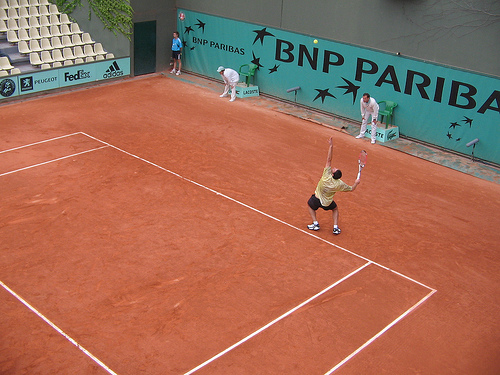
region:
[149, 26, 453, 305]
a man playing tennis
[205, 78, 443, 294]
a man on a tennis court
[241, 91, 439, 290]
a man on a dirt tennis court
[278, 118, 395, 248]
a man holding a racket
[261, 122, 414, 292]
a man holding a tennis racket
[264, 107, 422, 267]
a man swinging a racket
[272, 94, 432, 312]
a man swinging a tennis racket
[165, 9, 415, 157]
poeple standing on the side lines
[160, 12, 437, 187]
three people standing on the sidelines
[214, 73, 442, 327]
a man wearing a shirt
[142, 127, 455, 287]
a man is playing tennis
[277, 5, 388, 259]
the man is going to hit the ball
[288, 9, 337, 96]
the ball is lime green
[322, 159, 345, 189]
the man has dark hair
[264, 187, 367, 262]
the man is wearing shorts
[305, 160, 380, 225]
the man is wearing short sleeves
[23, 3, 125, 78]
the seats are empty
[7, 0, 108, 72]
the chairs are creme colored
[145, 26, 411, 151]
people standing in the background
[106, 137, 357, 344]
the ground is reddish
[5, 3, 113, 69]
rows of empty white seats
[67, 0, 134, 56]
green ivy on wall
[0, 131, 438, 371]
white lines on court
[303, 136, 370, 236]
player in a serving stance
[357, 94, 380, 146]
man in white bent over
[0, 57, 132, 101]
logos on green wall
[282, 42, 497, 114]
black letter on green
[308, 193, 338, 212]
black shorts on player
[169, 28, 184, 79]
person standing in corner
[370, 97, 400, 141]
green chair on block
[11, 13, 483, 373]
Tennis match on clay court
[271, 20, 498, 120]
BNP Paribas sponsorship sign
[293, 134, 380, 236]
Male tennis player in shorts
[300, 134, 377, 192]
Male tennis player serving ball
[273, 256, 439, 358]
White chalked side lines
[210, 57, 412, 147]
Two umpires watching match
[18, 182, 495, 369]
Red clay tennis court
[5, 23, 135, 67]
White empty seated stands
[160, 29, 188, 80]
Blue and black clad ball boy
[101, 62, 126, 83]
Black adidas sign and logo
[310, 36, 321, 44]
a small green tennis ball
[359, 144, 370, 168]
a red, white and blue racket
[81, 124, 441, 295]
a long white line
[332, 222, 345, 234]
the shoe of a man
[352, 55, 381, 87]
a black capital letter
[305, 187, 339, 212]
a man's black shorts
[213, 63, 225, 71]
a blue baseball cap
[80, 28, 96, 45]
a white seat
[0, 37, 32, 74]
part of a stairway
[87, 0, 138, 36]
green tree leaves